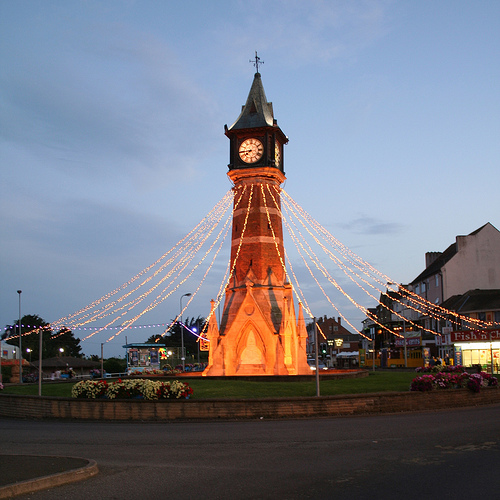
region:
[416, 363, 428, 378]
part of a house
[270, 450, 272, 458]
edge of a road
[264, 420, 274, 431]
part of a gradd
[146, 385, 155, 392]
part of a grass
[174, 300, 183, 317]
part of a cloud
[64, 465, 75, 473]
part of a pavement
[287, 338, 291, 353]
part of a grass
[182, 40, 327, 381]
a tower on garden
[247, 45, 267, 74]
the weathervane on top of tower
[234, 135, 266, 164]
the clock in front the tower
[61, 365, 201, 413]
white and red flowers in garden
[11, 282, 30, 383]
a light on pole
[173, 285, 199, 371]
a light on pole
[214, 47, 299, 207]
a steeple on a tower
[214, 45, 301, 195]
steeple is color black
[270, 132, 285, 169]
a clock on side the tower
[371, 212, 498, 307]
roof of building is black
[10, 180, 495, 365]
christmas lights leading to tower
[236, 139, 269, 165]
round white clock face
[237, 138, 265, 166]
time reading 9:40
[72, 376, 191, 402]
white bushes with red flowers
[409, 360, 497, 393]
salmon and pink bundles of flowers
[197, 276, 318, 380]
lighted alter arches surrounding tower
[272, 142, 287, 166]
white clock face in side of tower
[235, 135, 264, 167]
black roman numerals on face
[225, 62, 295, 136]
pointed green top of clock tower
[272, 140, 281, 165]
roman numerals in white clock face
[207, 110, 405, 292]
a clock is at the top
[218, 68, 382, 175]
the top of the tower, points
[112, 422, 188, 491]
the ground is gray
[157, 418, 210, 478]
cracks are in the ground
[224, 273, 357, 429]
the tower is illuminated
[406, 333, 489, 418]
the flowers are pink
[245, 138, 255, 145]
roman numeral on clock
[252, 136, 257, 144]
roman numeral on clock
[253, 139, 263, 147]
roman numeral on clock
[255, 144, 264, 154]
roman numeral on clock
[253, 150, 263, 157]
roman numeral on clock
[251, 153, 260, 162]
roman numeral on clock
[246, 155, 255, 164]
roman numeral on clock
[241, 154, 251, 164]
roman numeral on clock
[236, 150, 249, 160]
roman numeral on clock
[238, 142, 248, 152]
roman numeral on clock